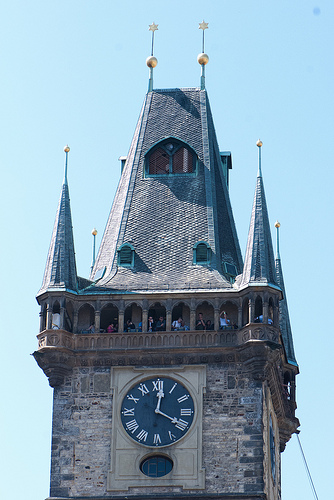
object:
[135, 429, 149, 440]
details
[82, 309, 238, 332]
people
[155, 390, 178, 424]
hand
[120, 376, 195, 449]
face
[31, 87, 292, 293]
shingles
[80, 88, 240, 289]
roof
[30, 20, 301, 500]
building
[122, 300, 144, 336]
window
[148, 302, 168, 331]
window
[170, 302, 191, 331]
window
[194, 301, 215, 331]
window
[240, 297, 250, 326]
window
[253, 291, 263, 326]
window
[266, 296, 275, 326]
window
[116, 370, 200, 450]
clock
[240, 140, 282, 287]
steeple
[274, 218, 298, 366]
steeple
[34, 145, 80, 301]
steeple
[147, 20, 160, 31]
star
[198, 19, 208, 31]
star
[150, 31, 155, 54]
pole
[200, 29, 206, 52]
pole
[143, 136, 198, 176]
window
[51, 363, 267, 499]
brick section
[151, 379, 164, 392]
number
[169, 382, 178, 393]
number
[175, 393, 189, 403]
number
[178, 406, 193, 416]
number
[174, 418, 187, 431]
number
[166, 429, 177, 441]
number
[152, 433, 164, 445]
number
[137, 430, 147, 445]
number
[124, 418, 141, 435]
number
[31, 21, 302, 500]
tower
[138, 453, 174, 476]
window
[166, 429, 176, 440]
numeral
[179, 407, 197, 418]
numeral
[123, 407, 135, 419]
numeral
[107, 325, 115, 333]
shirt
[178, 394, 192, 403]
numeral